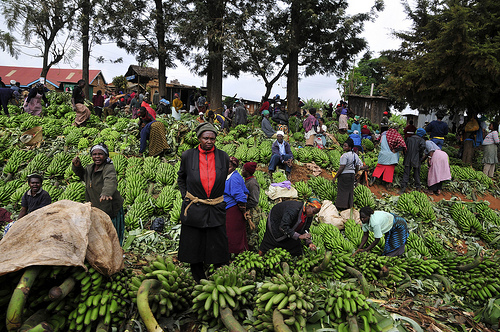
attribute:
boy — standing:
[8, 162, 66, 217]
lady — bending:
[258, 195, 322, 257]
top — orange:
[186, 140, 224, 201]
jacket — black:
[168, 140, 238, 266]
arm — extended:
[99, 166, 119, 193]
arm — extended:
[74, 165, 86, 181]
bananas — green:
[6, 67, 498, 330]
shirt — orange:
[195, 146, 218, 196]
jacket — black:
[174, 148, 229, 224]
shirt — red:
[198, 147, 217, 198]